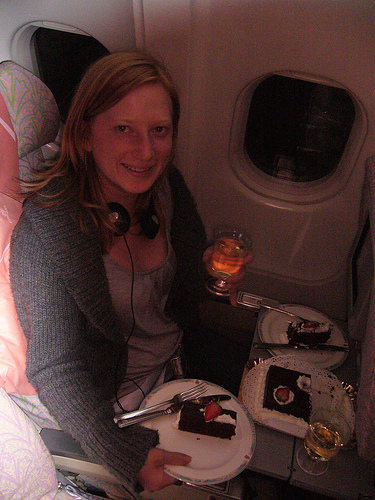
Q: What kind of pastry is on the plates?
A: Cake.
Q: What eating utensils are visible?
A: Knives and forks.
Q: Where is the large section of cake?
A: On a lace-like tray.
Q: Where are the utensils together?
A: On the plate the woman holds.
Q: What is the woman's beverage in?
A: A chalice.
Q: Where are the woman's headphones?
A: On the neck.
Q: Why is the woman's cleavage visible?
A: Low cut shirt.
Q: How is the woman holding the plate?
A: Right hand.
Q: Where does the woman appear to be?
A: Airplane.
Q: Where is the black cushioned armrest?
A: Under the woman's right wrist.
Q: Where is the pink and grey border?
A: The rim of the paper plate.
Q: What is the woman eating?
A: Cake.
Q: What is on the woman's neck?
A: Headphones.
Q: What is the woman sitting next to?
A: A window.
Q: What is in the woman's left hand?
A: A drink.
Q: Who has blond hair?
A: The woman.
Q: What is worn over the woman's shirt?
A: A blue sweater.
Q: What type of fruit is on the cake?
A: A strawberry.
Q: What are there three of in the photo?
A: Plates.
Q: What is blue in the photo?
A: The sweater.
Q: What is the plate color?
A: White.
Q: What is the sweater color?
A: Grey.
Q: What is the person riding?
A: Plane.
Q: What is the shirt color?
A: Grey.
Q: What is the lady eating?
A: She is eating a cake.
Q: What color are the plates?
A: The plates are white.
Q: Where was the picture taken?
A: This picture was taken on the plane.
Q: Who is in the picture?
A: A woman is in the picture.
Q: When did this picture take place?
A: This picture took place on the plane.